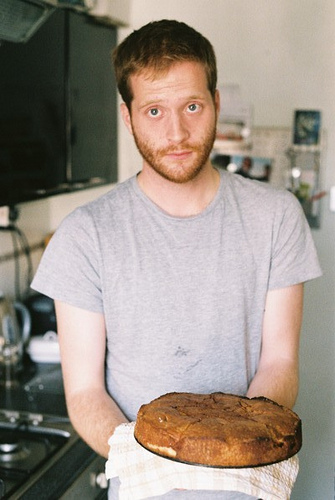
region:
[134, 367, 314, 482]
Lovely golden brown bread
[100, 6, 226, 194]
Man with brown hair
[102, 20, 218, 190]
Man with lots of facial hair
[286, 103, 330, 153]
Picture on the wall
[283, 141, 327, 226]
Picture on the wall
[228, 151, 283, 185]
Picture on the wall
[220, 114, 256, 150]
Picture on the wall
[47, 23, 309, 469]
Man in grey shirt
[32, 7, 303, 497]
Man holding a pastry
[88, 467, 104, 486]
White button to a stove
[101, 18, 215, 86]
man has brown hair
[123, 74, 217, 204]
man has red beard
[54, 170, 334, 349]
man has grey shirt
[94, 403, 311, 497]
man holds white cloth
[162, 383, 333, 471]
brown bread on white cloth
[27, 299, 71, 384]
white butter container behind man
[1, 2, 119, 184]
black cabinet behind man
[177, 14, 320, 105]
white wall behind man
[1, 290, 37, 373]
tea kettle behind man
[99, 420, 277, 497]
brown stripes on cloth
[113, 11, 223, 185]
a man with a beard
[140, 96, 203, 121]
a person with blue eyes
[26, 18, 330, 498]
a man holding a cake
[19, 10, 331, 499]
a person wearing a gray t shirt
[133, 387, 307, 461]
a delicious looking cake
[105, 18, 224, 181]
a red headed person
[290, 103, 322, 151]
a picture on the wall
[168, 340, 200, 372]
a stain on a grey t shirt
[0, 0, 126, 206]
a black cabinet in the background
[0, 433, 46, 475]
the element of a stove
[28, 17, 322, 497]
a man in a gray t-shirt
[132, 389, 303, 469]
a freshly baked cake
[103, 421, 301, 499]
a white kitchen towel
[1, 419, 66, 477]
a gas burner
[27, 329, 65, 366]
a white container with a lid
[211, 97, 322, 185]
blurry pictures on the walls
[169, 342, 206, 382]
small stains on the front of his shirt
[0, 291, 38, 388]
a blender on the counter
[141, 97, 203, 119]
blue eyes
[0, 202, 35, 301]
wires hanging down on the wall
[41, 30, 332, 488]
a man holding a circle cake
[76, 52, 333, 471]
a man holding a cooked cake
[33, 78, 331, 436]
a man holding a baked cake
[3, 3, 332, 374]
a man in a kitchen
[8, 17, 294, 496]
a man in a kitchen with a cake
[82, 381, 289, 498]
a cake on a towl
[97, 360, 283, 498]
a baked cake on a towl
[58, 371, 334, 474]
a cook caked on a towl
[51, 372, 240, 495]
a towel with a cake